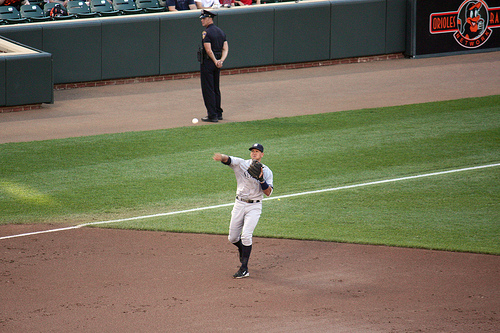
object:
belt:
[235, 196, 260, 203]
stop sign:
[219, 198, 268, 248]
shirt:
[222, 155, 275, 203]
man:
[209, 144, 272, 277]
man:
[194, 9, 229, 121]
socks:
[239, 243, 252, 269]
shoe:
[233, 266, 249, 279]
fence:
[0, 0, 499, 113]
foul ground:
[0, 54, 499, 333]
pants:
[228, 198, 263, 243]